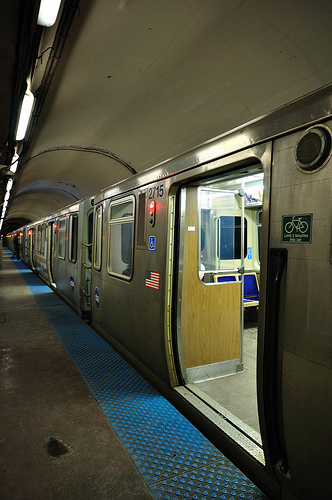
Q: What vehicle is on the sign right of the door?
A: Bicycle.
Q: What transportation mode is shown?
A: Subway.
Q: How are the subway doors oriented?
A: Open.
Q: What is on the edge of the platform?
A: Blue stripe.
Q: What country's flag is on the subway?
A: USA.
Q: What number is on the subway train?
A: 2715.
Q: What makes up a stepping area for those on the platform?
A: A blue textured surface.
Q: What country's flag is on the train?
A: United States.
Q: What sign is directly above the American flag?
A: A handicap sign.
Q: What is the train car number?
A: 2715.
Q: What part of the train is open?
A: The doors.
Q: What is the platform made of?
A: Cement.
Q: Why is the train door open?
A: To deboard or board passengers.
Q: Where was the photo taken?
A: Subway.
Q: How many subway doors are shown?
A: At least four.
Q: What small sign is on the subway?
A: Bicycle sign.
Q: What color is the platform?
A: Blue and grey.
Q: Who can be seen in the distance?
A: A man boarding the train.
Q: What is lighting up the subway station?
A: Fluorescent ceiling lights.